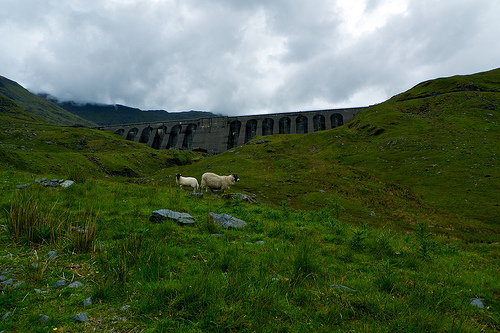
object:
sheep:
[199, 170, 237, 191]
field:
[5, 98, 493, 331]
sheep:
[176, 172, 201, 191]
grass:
[348, 142, 477, 227]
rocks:
[209, 208, 248, 234]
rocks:
[148, 207, 195, 230]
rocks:
[57, 176, 79, 191]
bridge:
[101, 107, 364, 153]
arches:
[231, 122, 239, 149]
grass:
[13, 189, 336, 329]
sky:
[2, 2, 493, 106]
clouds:
[228, 12, 295, 90]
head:
[232, 171, 243, 184]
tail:
[195, 179, 201, 190]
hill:
[2, 75, 173, 166]